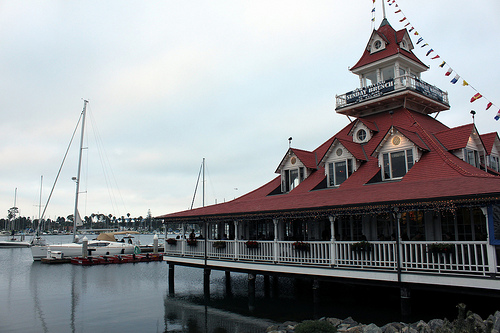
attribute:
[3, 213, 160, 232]
trees — dark, distant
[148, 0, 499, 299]
building — red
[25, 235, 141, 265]
boat — white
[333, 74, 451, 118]
platform — small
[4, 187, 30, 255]
sailboat — small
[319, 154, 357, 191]
windows — triple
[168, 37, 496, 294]
building — restaurant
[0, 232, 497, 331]
water — calm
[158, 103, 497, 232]
roof — steep, red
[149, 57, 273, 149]
sky — clear, blue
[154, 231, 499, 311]
porch — wraparound, white